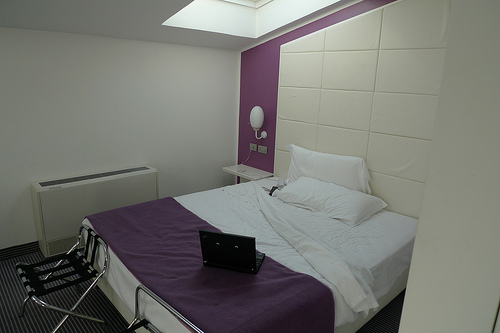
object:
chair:
[14, 223, 108, 330]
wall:
[100, 50, 171, 144]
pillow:
[273, 179, 390, 227]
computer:
[196, 226, 267, 274]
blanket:
[174, 178, 379, 328]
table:
[220, 159, 274, 177]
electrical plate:
[257, 143, 270, 157]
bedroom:
[1, 0, 499, 331]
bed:
[78, 175, 419, 332]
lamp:
[245, 102, 270, 141]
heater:
[30, 162, 159, 259]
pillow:
[283, 139, 373, 176]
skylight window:
[160, 0, 340, 39]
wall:
[272, 0, 450, 219]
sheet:
[365, 225, 403, 254]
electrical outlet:
[248, 141, 259, 153]